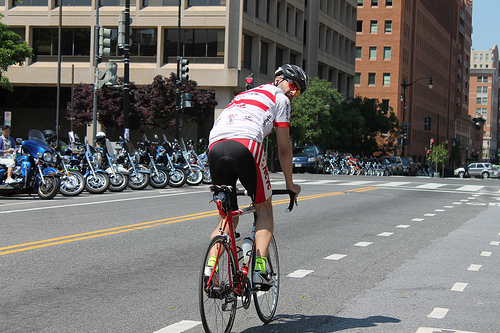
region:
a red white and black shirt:
[208, 87, 290, 142]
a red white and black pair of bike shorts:
[204, 134, 273, 205]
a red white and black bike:
[196, 178, 301, 328]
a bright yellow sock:
[252, 255, 264, 270]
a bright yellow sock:
[206, 256, 219, 271]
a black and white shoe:
[203, 264, 220, 288]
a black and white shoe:
[248, 268, 275, 284]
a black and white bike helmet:
[277, 63, 309, 89]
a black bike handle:
[270, 185, 301, 211]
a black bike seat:
[207, 180, 235, 194]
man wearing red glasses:
[195, 62, 310, 272]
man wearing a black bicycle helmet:
[199, 60, 308, 293]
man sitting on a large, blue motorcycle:
[0, 119, 64, 198]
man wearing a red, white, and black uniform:
[189, 66, 309, 286]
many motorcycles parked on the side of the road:
[0, 128, 212, 205]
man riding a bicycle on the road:
[175, 65, 317, 331]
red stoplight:
[422, 136, 439, 178]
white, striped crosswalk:
[235, 166, 498, 198]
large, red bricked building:
[354, 0, 473, 170]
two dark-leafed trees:
[64, 69, 217, 171]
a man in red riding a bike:
[197, 64, 308, 330]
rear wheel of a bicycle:
[200, 235, 241, 332]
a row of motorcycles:
[0, 125, 205, 200]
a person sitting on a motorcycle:
[1, 125, 56, 203]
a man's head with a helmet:
[273, 64, 308, 101]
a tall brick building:
[354, 0, 471, 172]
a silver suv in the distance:
[454, 161, 492, 177]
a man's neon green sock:
[253, 253, 268, 270]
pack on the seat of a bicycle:
[210, 193, 230, 216]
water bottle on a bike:
[240, 236, 255, 268]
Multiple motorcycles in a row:
[0, 125, 200, 191]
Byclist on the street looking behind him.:
[190, 60, 312, 327]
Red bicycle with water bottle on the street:
[200, 181, 290, 323]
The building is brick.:
[359, 3, 472, 172]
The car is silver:
[455, 160, 488, 176]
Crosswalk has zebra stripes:
[305, 175, 492, 195]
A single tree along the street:
[430, 145, 446, 175]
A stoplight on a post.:
[92, 26, 113, 58]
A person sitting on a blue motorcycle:
[0, 126, 60, 196]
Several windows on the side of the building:
[319, 20, 357, 67]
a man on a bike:
[163, 41, 370, 328]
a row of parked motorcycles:
[1, 116, 222, 202]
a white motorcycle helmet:
[94, 128, 107, 141]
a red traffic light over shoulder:
[238, 67, 257, 94]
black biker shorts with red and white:
[193, 128, 289, 218]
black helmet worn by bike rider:
[272, 61, 312, 96]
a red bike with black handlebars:
[189, 180, 321, 331]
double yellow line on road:
[1, 180, 379, 273]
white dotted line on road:
[209, 183, 482, 331]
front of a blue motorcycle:
[7, 129, 60, 206]